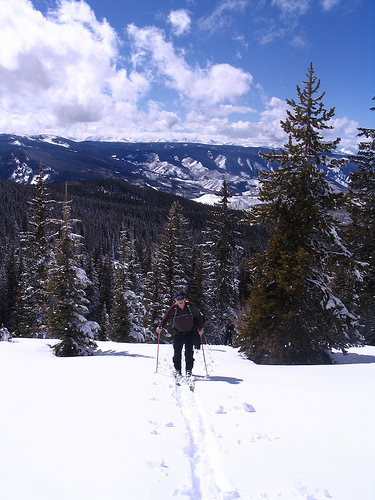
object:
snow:
[14, 162, 50, 184]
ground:
[6, 331, 374, 497]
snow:
[214, 153, 227, 170]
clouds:
[3, 1, 374, 155]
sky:
[3, 1, 375, 155]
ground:
[307, 147, 338, 174]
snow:
[182, 156, 201, 175]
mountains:
[0, 134, 372, 207]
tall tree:
[234, 53, 367, 366]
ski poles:
[156, 325, 160, 373]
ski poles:
[198, 327, 210, 378]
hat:
[171, 290, 186, 299]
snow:
[194, 193, 262, 208]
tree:
[144, 201, 204, 343]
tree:
[44, 180, 102, 356]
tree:
[235, 195, 339, 366]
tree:
[102, 290, 133, 342]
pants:
[169, 330, 194, 374]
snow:
[0, 343, 375, 499]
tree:
[201, 180, 244, 343]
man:
[156, 289, 205, 380]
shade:
[192, 373, 243, 384]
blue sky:
[237, 0, 372, 123]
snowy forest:
[2, 108, 375, 335]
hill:
[0, 336, 374, 498]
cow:
[176, 61, 259, 105]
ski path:
[173, 379, 236, 499]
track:
[174, 398, 189, 414]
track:
[203, 424, 223, 443]